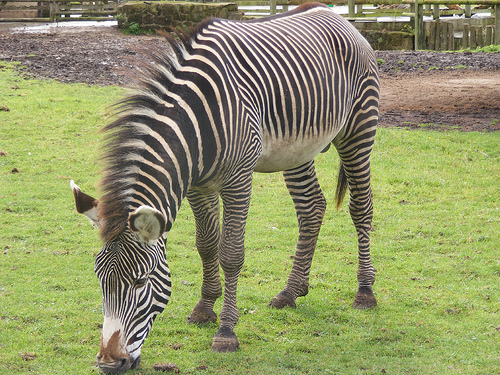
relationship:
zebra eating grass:
[69, 3, 384, 373] [3, 60, 500, 371]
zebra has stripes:
[69, 3, 384, 373] [155, 112, 197, 190]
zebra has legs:
[69, 3, 384, 373] [332, 84, 380, 308]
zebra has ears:
[69, 3, 384, 373] [127, 206, 165, 243]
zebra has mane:
[69, 3, 384, 373] [94, 19, 205, 251]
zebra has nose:
[69, 3, 384, 373] [95, 348, 134, 373]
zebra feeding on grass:
[69, 3, 384, 373] [3, 60, 500, 371]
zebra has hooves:
[69, 3, 384, 373] [352, 286, 377, 310]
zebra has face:
[69, 3, 384, 373] [94, 236, 155, 371]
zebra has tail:
[69, 3, 384, 373] [333, 151, 350, 210]